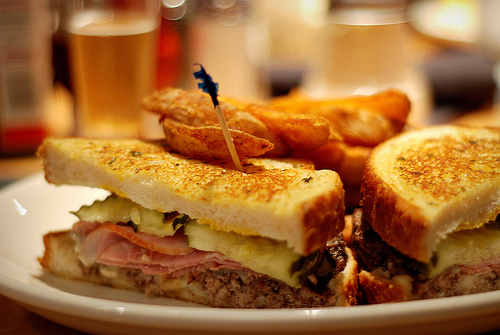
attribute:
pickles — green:
[70, 192, 322, 288]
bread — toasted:
[36, 124, 498, 306]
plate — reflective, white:
[2, 170, 499, 333]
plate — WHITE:
[5, 132, 498, 335]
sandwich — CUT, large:
[27, 120, 357, 335]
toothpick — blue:
[192, 62, 260, 174]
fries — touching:
[134, 61, 414, 201]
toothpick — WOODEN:
[182, 60, 249, 181]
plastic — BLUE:
[187, 59, 228, 99]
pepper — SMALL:
[298, 165, 314, 185]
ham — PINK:
[76, 216, 250, 266]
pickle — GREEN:
[66, 180, 187, 257]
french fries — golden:
[140, 85, 412, 214]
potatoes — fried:
[141, 87, 410, 214]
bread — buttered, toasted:
[359, 123, 498, 263]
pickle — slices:
[68, 194, 325, 284]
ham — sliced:
[100, 242, 240, 275]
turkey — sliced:
[108, 218, 196, 255]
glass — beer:
[65, 0, 160, 138]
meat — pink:
[98, 220, 230, 278]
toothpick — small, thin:
[191, 65, 253, 172]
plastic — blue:
[191, 63, 225, 109]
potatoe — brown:
[142, 80, 273, 150]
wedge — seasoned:
[142, 88, 278, 144]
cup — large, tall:
[60, 6, 157, 144]